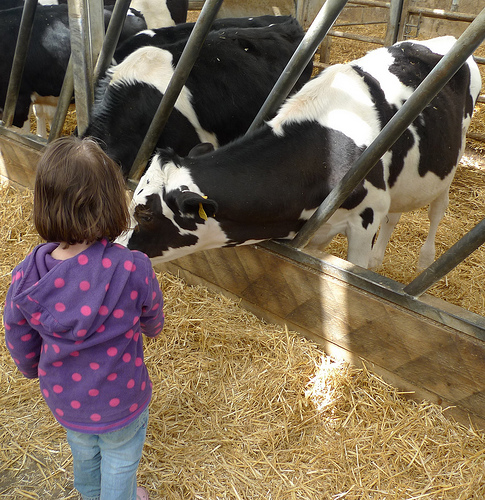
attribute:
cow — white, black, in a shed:
[104, 26, 483, 315]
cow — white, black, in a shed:
[58, 12, 315, 225]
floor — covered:
[0, 6, 483, 500]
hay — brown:
[1, 4, 483, 499]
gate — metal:
[1, 1, 485, 218]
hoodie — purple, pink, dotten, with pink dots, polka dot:
[2, 237, 165, 434]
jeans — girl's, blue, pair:
[61, 406, 151, 500]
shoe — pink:
[135, 480, 150, 499]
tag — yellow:
[196, 192, 211, 223]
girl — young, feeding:
[2, 132, 169, 500]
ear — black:
[172, 185, 219, 223]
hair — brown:
[28, 133, 151, 253]